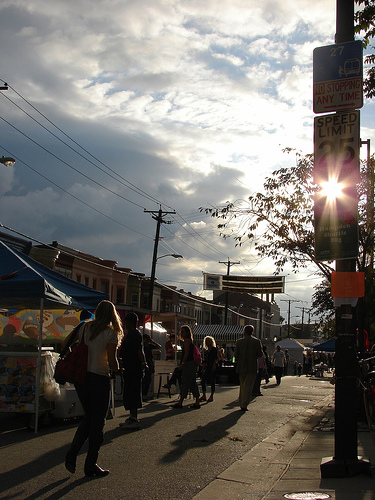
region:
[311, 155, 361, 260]
Sun reflecting on sign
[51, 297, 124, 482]
Woman carrying red bag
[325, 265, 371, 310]
Orange sign on pole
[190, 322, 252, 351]
Blue and white striped tent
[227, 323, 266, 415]
Man walking on road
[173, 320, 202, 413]
Woman wearing pink backpack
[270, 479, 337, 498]
Sewer top on sidewalk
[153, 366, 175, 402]
stool sitting in street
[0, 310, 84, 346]
illustration of different ice cream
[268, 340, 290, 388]
Man wearing white shirt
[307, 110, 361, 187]
25 Speed limit sign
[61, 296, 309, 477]
People walking in the street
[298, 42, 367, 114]
No stopping sign on the pole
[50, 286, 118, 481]
lady walking with a red bag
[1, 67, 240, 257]
Electric pole and electric wire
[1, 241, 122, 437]
food stand in the street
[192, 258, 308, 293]
banner hanging on the middle of the road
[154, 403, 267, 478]
man shadow on the street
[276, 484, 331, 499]
manhole on the side of the street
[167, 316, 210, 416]
lady standing with pink bag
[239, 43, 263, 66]
part of the sky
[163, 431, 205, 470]
part of a shade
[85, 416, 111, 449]
part of a trouser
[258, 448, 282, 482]
edge of a road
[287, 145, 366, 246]
bright glare from the sun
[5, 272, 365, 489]
people at a street market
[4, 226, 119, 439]
a blue pop up tent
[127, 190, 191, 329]
a tall power pole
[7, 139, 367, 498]
city street on a cloudy day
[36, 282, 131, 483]
a girl with a large bag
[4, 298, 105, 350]
a large building mural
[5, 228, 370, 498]
people on a busy street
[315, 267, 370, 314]
a handwritten sign on a street post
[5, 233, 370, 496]
people walking in town at sunset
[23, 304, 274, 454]
The people are walking